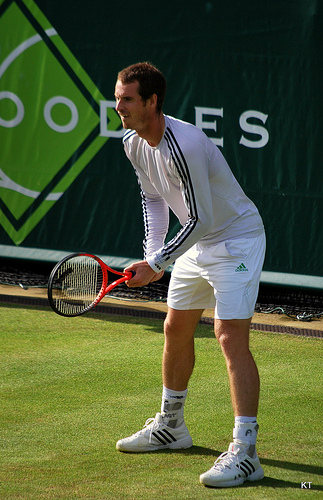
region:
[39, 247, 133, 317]
a red and black tennis racket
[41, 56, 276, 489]
a man bent forwards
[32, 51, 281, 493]
a person holding a tennis racket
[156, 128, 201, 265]
three black stripes on a white shirt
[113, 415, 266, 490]
a pair of white tennis shoes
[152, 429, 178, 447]
three black stripes on white shoes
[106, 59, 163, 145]
a man with brown hair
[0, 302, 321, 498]
a green tennis court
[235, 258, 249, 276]
a small green adidas label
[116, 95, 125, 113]
a man's pointy nose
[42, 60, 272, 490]
the tennis player is ready to hit the ball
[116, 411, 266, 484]
the player is wearing white tennis shoes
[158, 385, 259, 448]
a velcro splints are over the player's socks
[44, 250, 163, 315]
the tennis racket is black and orange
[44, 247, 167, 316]
the player is holding the racket with both hands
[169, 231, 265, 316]
white tennis shorts are on the player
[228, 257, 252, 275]
a green logo is on the shorts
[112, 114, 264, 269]
the man is wearing a long sleeved shirt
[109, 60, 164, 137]
the man has short brown hair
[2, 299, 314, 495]
the man is playing on a grass court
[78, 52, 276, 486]
Man wearing a white shirt with black stripes and white shorts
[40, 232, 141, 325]
Tennis racket with a red handle and black and red hea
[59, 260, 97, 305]
White strings of a tennis racket with a black logo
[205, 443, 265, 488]
White tennis shoe with multiple black stripes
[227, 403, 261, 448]
Black and white sock worn up the calf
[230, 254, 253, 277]
Green Adidas logo placed on white shorts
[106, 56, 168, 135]
Man with short brown hair with sunlight on his face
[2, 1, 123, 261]
Large light green triangle shaped logo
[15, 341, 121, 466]
Surface of ground in varying shades of green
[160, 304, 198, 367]
A man's tanned knee and thigh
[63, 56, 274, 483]
tennis player leaning forward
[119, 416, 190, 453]
white sneaker with black stripes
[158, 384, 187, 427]
tall white and grey sock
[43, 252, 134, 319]
black and red tennis racket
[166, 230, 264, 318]
shorts with a brand name symbol on them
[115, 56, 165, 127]
short dark brown hair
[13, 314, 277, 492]
grassy tennis court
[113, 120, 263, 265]
white shirt with black stripes on the sleeves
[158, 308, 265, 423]
bare legs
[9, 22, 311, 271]
dark and light green backdrop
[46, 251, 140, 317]
red and black tennis racket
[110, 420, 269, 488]
white tennis shoes with black adidas stripes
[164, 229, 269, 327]
white adidas shorts on tennis player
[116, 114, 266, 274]
white long sleeved adidas shirt with black stripes on sleeves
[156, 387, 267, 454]
black and gray socks on man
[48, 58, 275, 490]
white tennis player holding racket readying for play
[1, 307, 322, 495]
green grassy tennis court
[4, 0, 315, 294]
green fabric sign with sponsorship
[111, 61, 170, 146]
short brown hair on tennis player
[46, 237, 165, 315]
tennis racket held with both hands